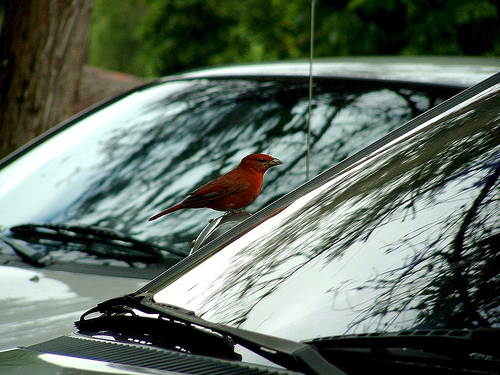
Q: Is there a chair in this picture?
A: No, there are no chairs.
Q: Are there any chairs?
A: No, there are no chairs.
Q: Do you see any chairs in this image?
A: No, there are no chairs.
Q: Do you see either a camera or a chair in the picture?
A: No, there are no chairs or cameras.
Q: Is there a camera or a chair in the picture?
A: No, there are no chairs or cameras.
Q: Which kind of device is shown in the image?
A: The device is a screen.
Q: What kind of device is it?
A: The device is a screen.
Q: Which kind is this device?
A: That is a screen.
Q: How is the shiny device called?
A: The device is a screen.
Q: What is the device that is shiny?
A: The device is a screen.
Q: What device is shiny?
A: The device is a screen.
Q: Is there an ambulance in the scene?
A: No, there are no ambulances.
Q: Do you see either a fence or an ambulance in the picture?
A: No, there are no ambulances or fences.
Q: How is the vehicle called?
A: The vehicle is a car.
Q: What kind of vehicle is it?
A: The vehicle is a car.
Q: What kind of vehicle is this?
A: This is a car.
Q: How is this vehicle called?
A: This is a car.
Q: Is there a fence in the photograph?
A: No, there are no fences.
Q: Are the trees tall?
A: Yes, the trees are tall.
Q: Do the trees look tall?
A: Yes, the trees are tall.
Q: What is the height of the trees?
A: The trees are tall.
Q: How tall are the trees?
A: The trees are tall.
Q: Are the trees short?
A: No, the trees are tall.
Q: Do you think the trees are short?
A: No, the trees are tall.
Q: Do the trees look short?
A: No, the trees are tall.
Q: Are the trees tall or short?
A: The trees are tall.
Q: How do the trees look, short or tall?
A: The trees are tall.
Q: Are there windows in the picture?
A: Yes, there is a window.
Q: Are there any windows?
A: Yes, there is a window.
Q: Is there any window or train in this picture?
A: Yes, there is a window.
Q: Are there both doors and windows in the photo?
A: No, there is a window but no doors.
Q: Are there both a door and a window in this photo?
A: No, there is a window but no doors.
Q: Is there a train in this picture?
A: No, there are no trains.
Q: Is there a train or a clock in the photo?
A: No, there are no trains or clocks.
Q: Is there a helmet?
A: No, there are no helmets.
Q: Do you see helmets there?
A: No, there are no helmets.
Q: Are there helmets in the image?
A: No, there are no helmets.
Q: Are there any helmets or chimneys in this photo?
A: No, there are no helmets or chimneys.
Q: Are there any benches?
A: No, there are no benches.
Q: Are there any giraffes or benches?
A: No, there are no benches or giraffes.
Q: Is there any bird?
A: Yes, there is a bird.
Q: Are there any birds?
A: Yes, there is a bird.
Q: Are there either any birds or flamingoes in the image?
A: Yes, there is a bird.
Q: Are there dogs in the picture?
A: No, there are no dogs.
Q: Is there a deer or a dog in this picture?
A: No, there are no dogs or deer.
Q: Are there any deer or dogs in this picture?
A: No, there are no dogs or deer.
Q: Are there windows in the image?
A: Yes, there is a window.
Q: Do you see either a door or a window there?
A: Yes, there is a window.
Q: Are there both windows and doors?
A: No, there is a window but no doors.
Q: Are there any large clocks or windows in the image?
A: Yes, there is a large window.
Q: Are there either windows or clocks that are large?
A: Yes, the window is large.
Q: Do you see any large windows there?
A: Yes, there is a large window.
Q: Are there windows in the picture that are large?
A: Yes, there is a large window.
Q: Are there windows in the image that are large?
A: Yes, there is a window that is large.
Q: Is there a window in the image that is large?
A: Yes, there is a window that is large.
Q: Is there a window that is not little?
A: Yes, there is a large window.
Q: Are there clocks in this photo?
A: No, there are no clocks.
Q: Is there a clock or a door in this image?
A: No, there are no clocks or doors.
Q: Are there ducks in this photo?
A: No, there are no ducks.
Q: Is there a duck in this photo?
A: No, there are no ducks.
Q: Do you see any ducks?
A: No, there are no ducks.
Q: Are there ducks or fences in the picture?
A: No, there are no ducks or fences.